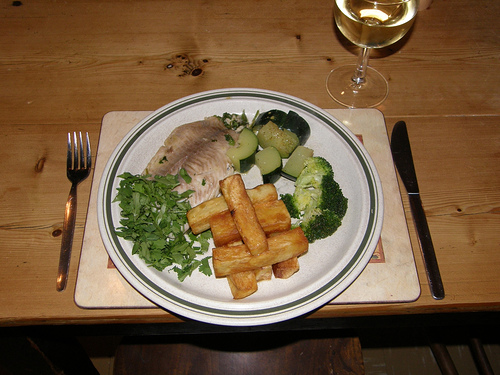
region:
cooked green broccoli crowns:
[280, 178, 348, 243]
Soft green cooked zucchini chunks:
[230, 108, 312, 183]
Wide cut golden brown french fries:
[186, 170, 310, 299]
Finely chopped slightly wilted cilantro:
[111, 170, 189, 283]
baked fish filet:
[140, 115, 240, 207]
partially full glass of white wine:
[324, 0, 419, 108]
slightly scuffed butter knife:
[389, 117, 446, 299]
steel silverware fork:
[51, 132, 93, 298]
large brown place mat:
[72, 105, 425, 308]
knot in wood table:
[162, 43, 212, 81]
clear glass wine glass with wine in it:
[323, 0, 420, 110]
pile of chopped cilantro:
[113, 168, 217, 278]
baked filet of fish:
[139, 114, 239, 207]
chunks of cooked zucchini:
[228, 106, 316, 184]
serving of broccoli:
[281, 154, 350, 241]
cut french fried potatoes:
[186, 172, 309, 299]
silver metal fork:
[53, 128, 94, 294]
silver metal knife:
[389, 118, 445, 298]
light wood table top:
[0, 1, 498, 326]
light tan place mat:
[71, 105, 423, 311]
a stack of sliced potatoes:
[183, 172, 308, 300]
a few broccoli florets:
[280, 156, 347, 242]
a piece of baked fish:
[141, 109, 238, 210]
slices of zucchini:
[224, 103, 316, 184]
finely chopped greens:
[111, 162, 216, 282]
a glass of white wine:
[325, 0, 416, 109]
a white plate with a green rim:
[95, 85, 385, 327]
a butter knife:
[386, 117, 449, 300]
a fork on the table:
[54, 126, 92, 293]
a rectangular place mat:
[72, 105, 421, 310]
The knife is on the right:
[360, 105, 473, 339]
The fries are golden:
[201, 169, 283, 296]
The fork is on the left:
[55, 108, 103, 317]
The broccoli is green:
[288, 158, 366, 248]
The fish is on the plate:
[120, 125, 223, 200]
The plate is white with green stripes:
[134, 104, 335, 327]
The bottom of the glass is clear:
[312, 47, 394, 119]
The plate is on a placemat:
[94, 89, 392, 373]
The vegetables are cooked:
[236, 101, 348, 208]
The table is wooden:
[52, 64, 137, 121]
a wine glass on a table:
[324, 1, 418, 110]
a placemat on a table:
[73, 107, 422, 308]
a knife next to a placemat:
[388, 117, 448, 298]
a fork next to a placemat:
[55, 128, 92, 294]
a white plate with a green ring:
[96, 86, 385, 327]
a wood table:
[0, 2, 497, 325]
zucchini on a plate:
[226, 108, 312, 186]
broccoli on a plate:
[280, 157, 349, 242]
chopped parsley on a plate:
[114, 171, 211, 284]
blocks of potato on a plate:
[185, 174, 309, 300]